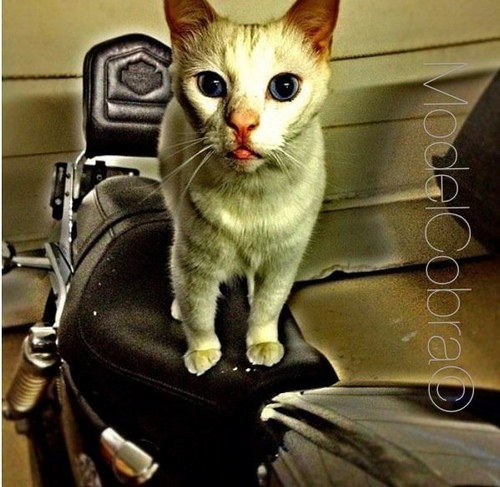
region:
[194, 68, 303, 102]
Large eyes of a white cat.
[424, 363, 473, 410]
Copyright symbol.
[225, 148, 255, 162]
Pink tongue of a cat.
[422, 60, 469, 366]
The word Model Cobra.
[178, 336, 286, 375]
Two front paws on a white and tan cat.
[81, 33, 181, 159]
Back black leather seat of a motorcycle.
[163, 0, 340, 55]
Two orange colored ears of a white cat.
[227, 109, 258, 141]
Nose on the face of a white cat.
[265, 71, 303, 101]
A cat's left eye.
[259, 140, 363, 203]
A cat's left side whiskers.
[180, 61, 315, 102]
The cat has blue eyes.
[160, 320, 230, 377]
The front left cat paw.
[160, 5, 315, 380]
The cat is standing up.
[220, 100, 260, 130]
The cat has a nose.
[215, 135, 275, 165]
The cat's mouth.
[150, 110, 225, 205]
Whiskers on a cat.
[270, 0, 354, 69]
The ear on a cat.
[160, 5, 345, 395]
The cat is white.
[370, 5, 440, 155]
The wall is white.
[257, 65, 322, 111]
A blue cat eye.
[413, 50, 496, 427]
copyright mark on side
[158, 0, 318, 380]
cat sitting on back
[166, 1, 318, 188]
cat sticking tongue out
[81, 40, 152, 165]
back of motorcycle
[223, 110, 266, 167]
pink cat nose and tongue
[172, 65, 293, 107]
blue eyes of cat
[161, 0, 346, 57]
pointy ears of cat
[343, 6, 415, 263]
white paneling of wall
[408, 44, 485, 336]
copyright mark text is white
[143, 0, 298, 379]
cat color is orange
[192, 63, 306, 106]
the pussy cat has blue eyes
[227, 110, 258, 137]
the cat has a pink nose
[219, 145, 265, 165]
the cat's tongue is hanging out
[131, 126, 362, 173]
white whiskers are on the cat's cheeks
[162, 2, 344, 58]
the ears are pink on the cat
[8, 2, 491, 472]
the motorcycle has a cat standing on it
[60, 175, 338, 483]
the seat on the bike is black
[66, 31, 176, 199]
the cycle has a backrest for a passenger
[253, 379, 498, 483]
the gas tank is a shiny black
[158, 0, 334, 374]
the cat is white with gray stripes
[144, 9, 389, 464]
cat standing on motorcycle seat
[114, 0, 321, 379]
white cat in photograph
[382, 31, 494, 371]
white writing on photo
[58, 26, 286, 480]
motorcycle seat with white cat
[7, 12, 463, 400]
white wall behind white cat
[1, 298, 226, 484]
silver metal on black motorcycle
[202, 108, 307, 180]
cat sticking tongue out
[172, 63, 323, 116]
white cat with blue eyes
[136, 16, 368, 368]
white cat looking at photographer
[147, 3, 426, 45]
ears visible in photograph